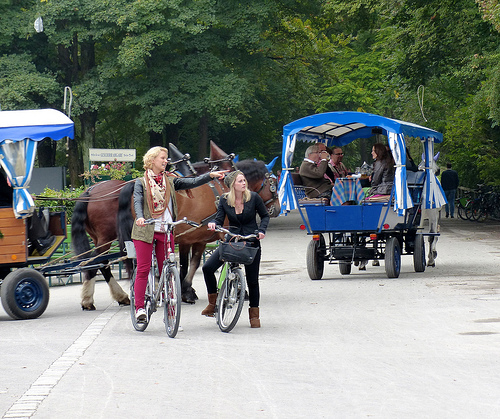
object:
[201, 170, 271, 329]
woman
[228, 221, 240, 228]
black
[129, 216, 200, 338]
bikes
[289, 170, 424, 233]
carriage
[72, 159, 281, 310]
horse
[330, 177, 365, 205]
tablecloth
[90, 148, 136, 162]
sign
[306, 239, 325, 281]
wheels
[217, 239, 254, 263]
basket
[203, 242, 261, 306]
jeans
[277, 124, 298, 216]
curtains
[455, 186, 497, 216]
railing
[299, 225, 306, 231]
reflectors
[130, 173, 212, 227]
jacket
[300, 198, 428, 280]
wagon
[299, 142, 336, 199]
man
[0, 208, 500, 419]
road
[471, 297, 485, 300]
mark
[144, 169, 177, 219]
scarf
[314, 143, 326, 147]
hat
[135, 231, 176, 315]
pants